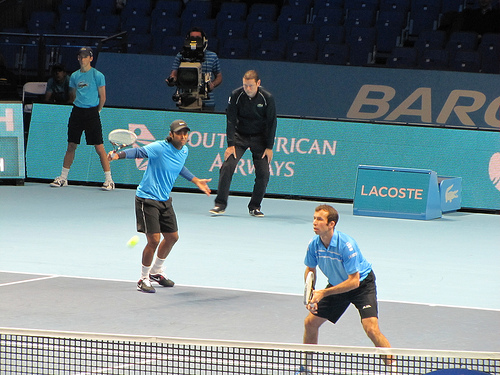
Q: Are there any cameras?
A: Yes, there is a camera.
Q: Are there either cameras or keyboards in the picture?
A: Yes, there is a camera.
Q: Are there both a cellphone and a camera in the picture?
A: No, there is a camera but no cell phones.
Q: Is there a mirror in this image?
A: No, there are no mirrors.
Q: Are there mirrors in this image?
A: No, there are no mirrors.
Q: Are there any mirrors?
A: No, there are no mirrors.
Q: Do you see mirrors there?
A: No, there are no mirrors.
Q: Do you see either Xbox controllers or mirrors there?
A: No, there are no mirrors or Xbox controllers.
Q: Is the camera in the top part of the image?
A: Yes, the camera is in the top of the image.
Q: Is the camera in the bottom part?
A: No, the camera is in the top of the image.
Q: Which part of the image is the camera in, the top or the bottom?
A: The camera is in the top of the image.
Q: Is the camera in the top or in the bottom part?
A: The camera is in the top of the image.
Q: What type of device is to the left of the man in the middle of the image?
A: The device is a camera.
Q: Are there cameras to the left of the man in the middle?
A: Yes, there is a camera to the left of the man.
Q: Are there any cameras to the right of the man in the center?
A: No, the camera is to the left of the man.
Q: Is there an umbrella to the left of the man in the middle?
A: No, there is a camera to the left of the man.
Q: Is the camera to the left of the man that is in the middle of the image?
A: Yes, the camera is to the left of the man.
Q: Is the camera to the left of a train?
A: No, the camera is to the left of the man.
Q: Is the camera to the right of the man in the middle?
A: No, the camera is to the left of the man.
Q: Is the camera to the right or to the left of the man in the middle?
A: The camera is to the left of the man.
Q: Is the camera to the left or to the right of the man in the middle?
A: The camera is to the left of the man.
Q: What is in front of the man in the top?
A: The camera is in front of the man.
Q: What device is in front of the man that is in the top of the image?
A: The device is a camera.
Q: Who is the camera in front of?
A: The camera is in front of the man.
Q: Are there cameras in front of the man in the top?
A: Yes, there is a camera in front of the man.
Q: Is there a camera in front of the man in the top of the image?
A: Yes, there is a camera in front of the man.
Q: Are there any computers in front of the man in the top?
A: No, there is a camera in front of the man.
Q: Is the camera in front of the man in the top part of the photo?
A: Yes, the camera is in front of the man.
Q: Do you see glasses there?
A: No, there are no glasses.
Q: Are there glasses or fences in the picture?
A: No, there are no glasses or fences.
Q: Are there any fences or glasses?
A: No, there are no glasses or fences.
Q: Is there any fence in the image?
A: No, there are no fences.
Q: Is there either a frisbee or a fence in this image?
A: No, there are no fences or frisbees.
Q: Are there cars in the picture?
A: No, there are no cars.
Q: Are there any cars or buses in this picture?
A: No, there are no cars or buses.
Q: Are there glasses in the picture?
A: No, there are no glasses.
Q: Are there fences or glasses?
A: No, there are no glasses or fences.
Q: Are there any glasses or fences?
A: No, there are no glasses or fences.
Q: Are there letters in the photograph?
A: Yes, there are letters.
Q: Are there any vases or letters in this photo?
A: Yes, there are letters.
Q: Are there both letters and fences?
A: No, there are letters but no fences.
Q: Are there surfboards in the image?
A: No, there are no surfboards.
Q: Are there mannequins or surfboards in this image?
A: No, there are no surfboards or mannequins.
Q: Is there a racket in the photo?
A: Yes, there are rackets.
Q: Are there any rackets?
A: Yes, there are rackets.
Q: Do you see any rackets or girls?
A: Yes, there are rackets.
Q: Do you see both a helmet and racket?
A: No, there are rackets but no helmets.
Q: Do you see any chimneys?
A: No, there are no chimneys.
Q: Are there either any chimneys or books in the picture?
A: No, there are no chimneys or books.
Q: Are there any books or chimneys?
A: No, there are no chimneys or books.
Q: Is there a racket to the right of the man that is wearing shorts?
A: Yes, there are rackets to the right of the man.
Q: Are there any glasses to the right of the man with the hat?
A: No, there are rackets to the right of the man.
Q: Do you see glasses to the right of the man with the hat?
A: No, there are rackets to the right of the man.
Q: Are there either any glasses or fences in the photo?
A: No, there are no glasses or fences.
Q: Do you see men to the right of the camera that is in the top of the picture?
A: Yes, there is a man to the right of the camera.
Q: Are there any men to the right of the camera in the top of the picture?
A: Yes, there is a man to the right of the camera.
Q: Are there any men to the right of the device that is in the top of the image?
A: Yes, there is a man to the right of the camera.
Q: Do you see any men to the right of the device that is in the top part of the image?
A: Yes, there is a man to the right of the camera.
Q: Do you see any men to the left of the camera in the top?
A: No, the man is to the right of the camera.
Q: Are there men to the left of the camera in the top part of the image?
A: No, the man is to the right of the camera.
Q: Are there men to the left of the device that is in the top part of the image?
A: No, the man is to the right of the camera.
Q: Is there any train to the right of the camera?
A: No, there is a man to the right of the camera.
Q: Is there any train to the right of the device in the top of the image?
A: No, there is a man to the right of the camera.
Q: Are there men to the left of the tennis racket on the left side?
A: No, the man is to the right of the tennis racket.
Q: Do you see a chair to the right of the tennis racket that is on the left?
A: No, there is a man to the right of the tennis racket.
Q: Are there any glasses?
A: No, there are no glasses.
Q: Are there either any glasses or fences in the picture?
A: No, there are no glasses or fences.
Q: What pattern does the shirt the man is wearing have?
A: The shirt has striped pattern.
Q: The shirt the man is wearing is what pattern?
A: The shirt is striped.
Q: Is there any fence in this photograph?
A: No, there are no fences.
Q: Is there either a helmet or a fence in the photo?
A: No, there are no fences or helmets.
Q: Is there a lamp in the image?
A: No, there are no lamps.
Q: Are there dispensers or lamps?
A: No, there are no lamps or dispensers.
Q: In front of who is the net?
A: The net is in front of the people.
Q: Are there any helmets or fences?
A: No, there are no fences or helmets.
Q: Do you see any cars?
A: No, there are no cars.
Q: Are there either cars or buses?
A: No, there are no cars or buses.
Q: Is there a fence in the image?
A: No, there are no fences.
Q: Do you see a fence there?
A: No, there are no fences.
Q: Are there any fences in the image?
A: No, there are no fences.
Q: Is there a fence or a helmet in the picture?
A: No, there are no fences or helmets.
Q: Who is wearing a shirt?
A: The man is wearing a shirt.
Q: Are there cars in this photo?
A: No, there are no cars.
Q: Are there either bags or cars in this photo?
A: No, there are no cars or bags.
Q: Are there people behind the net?
A: Yes, there are people behind the net.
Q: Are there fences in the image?
A: No, there are no fences.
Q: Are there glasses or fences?
A: No, there are no fences or glasses.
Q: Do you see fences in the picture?
A: No, there are no fences.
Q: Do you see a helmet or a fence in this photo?
A: No, there are no fences or helmets.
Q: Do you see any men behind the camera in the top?
A: Yes, there is a man behind the camera.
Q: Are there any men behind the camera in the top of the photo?
A: Yes, there is a man behind the camera.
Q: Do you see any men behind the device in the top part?
A: Yes, there is a man behind the camera.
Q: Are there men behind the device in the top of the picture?
A: Yes, there is a man behind the camera.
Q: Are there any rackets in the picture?
A: Yes, there is a racket.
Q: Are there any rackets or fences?
A: Yes, there is a racket.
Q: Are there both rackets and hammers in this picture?
A: No, there is a racket but no hammers.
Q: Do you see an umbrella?
A: No, there are no umbrellas.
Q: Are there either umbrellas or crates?
A: No, there are no umbrellas or crates.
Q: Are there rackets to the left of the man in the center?
A: Yes, there is a racket to the left of the man.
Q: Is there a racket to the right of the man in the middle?
A: No, the racket is to the left of the man.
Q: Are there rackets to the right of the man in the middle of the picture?
A: No, the racket is to the left of the man.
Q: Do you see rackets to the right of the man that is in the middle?
A: No, the racket is to the left of the man.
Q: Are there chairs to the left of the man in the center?
A: No, there is a racket to the left of the man.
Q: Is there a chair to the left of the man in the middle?
A: No, there is a racket to the left of the man.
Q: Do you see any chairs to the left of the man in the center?
A: No, there is a racket to the left of the man.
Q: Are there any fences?
A: No, there are no fences.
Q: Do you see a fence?
A: No, there are no fences.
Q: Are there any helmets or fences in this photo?
A: No, there are no fences or helmets.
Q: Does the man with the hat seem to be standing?
A: Yes, the man is standing.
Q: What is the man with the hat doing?
A: The man is standing.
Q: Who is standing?
A: The man is standing.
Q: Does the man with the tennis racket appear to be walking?
A: No, the man is standing.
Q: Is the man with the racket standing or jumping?
A: The man is standing.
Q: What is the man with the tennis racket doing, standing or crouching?
A: The man is standing.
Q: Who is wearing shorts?
A: The man is wearing shorts.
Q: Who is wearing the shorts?
A: The man is wearing shorts.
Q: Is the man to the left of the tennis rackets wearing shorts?
A: Yes, the man is wearing shorts.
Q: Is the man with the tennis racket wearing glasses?
A: No, the man is wearing shorts.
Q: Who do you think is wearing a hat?
A: The man is wearing a hat.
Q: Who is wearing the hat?
A: The man is wearing a hat.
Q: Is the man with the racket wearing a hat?
A: Yes, the man is wearing a hat.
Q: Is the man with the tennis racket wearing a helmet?
A: No, the man is wearing a hat.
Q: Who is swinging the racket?
A: The man is swinging the racket.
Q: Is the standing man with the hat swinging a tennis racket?
A: Yes, the man is swinging a tennis racket.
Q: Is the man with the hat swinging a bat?
A: No, the man is swinging a tennis racket.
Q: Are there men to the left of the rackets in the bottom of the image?
A: Yes, there is a man to the left of the tennis rackets.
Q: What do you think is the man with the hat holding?
A: The man is holding the tennis racket.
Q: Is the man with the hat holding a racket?
A: Yes, the man is holding a racket.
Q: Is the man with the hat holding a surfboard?
A: No, the man is holding a racket.